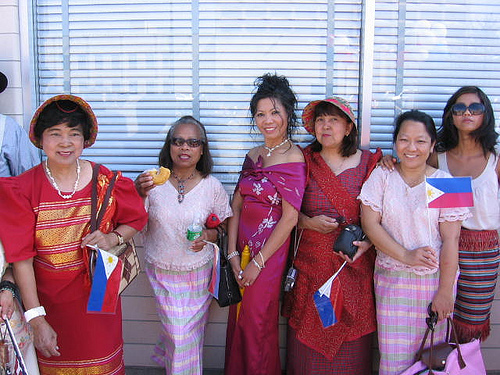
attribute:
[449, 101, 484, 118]
glasses — sun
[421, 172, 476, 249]
flag — small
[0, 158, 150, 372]
dress — red, gold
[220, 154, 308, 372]
dress — party, pink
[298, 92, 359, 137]
hat — red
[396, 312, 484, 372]
purse — pink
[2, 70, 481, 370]
women — in dresses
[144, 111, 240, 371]
woman — holding a donut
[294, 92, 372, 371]
woman — holding a flag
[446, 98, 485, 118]
woman — wearing sunglasses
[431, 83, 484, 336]
woman — wearing a striped skirt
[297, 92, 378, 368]
woman — wearing a hat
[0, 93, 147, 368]
woman — with a flag, wearing a necklace, holding a purse and a flag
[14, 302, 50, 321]
bracelet — on a woman's wrist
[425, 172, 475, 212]
flag — red, white, and blue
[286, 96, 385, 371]
lady — holding a flag and purse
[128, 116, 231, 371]
lady — holding food in her hand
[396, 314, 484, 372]
large/pink bag — with brown handle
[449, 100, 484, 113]
dark sunglasses — large, round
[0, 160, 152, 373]
red dress — with gold stripes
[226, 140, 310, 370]
long/pink dress — with flowers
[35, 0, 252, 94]
reflections — in the window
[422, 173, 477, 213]
flag — with three colors,  foreign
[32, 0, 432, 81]
window — with the shades down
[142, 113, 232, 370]
woman — wearing black sunglasses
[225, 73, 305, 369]
woman — in a pink dress, with her hair up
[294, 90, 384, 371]
woman — older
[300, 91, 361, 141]
hat — sun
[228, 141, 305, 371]
dress — pink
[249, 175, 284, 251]
design — floral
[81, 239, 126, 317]
flag —  foreign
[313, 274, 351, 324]
flag —  foreign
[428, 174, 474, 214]
flag —  foreign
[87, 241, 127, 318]
flag —  foreign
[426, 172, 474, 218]
flag —  foreign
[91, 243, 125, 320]
flag —  foreign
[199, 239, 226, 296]
flag —  foreign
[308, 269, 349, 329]
flag —  foreign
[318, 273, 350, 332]
flag —  foreign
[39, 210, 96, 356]
dress — gold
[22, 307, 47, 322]
bracelet — thick, white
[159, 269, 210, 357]
skirt — plaid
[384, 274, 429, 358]
skirt — plaid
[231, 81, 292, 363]
woman — strapless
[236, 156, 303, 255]
dress — pink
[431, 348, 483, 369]
tote bag — pink